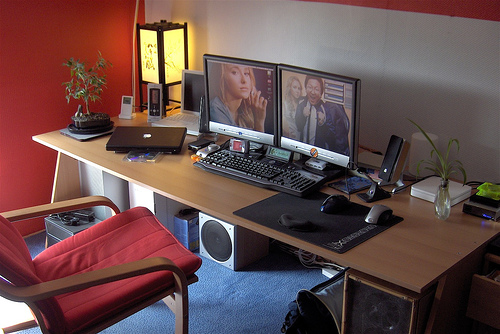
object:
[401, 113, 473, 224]
plant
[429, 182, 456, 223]
vase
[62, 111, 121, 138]
vase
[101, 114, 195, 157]
laptop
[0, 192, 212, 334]
chair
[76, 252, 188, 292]
frame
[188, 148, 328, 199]
keyboard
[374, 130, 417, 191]
subwoofer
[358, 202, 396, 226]
mice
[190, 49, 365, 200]
computers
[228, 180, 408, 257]
mouse pad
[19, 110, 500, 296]
desk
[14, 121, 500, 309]
work station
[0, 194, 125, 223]
wooden handles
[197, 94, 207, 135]
speaker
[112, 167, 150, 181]
wood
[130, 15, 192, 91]
lamp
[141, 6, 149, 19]
corner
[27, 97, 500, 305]
table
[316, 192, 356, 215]
computer mice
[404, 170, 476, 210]
router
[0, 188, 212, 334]
seat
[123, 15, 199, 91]
light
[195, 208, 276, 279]
speaker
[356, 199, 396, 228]
mouse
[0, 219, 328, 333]
floor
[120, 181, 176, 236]
device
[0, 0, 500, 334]
room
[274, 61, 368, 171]
screens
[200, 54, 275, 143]
monitor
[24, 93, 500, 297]
counter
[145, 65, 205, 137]
computer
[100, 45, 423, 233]
items